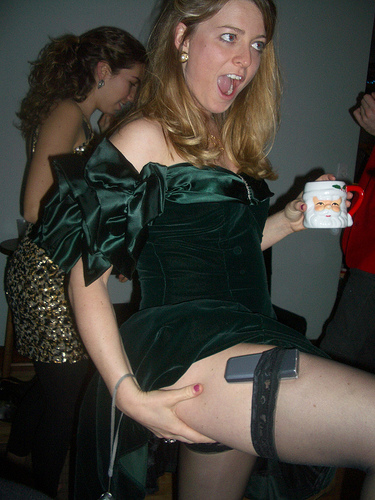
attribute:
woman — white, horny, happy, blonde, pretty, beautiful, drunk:
[34, 0, 374, 499]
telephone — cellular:
[222, 344, 304, 385]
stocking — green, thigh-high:
[246, 345, 371, 500]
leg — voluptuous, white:
[149, 330, 374, 499]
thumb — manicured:
[167, 381, 206, 409]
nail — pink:
[192, 382, 201, 392]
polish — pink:
[193, 382, 201, 396]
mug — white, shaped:
[300, 177, 365, 232]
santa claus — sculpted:
[299, 178, 348, 231]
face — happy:
[166, 1, 269, 120]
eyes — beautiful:
[217, 30, 267, 55]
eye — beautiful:
[217, 31, 241, 46]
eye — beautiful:
[249, 36, 267, 56]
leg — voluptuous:
[169, 430, 264, 498]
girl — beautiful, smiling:
[5, 19, 149, 498]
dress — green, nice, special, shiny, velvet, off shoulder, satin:
[30, 128, 340, 499]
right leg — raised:
[141, 303, 375, 498]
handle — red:
[344, 184, 365, 217]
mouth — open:
[211, 69, 248, 102]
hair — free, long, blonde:
[141, 2, 283, 186]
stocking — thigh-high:
[175, 437, 254, 499]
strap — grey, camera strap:
[105, 369, 137, 479]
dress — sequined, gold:
[5, 108, 91, 368]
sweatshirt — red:
[339, 125, 375, 274]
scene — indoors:
[7, 1, 373, 498]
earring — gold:
[175, 49, 190, 65]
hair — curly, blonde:
[11, 19, 150, 164]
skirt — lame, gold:
[2, 225, 92, 367]